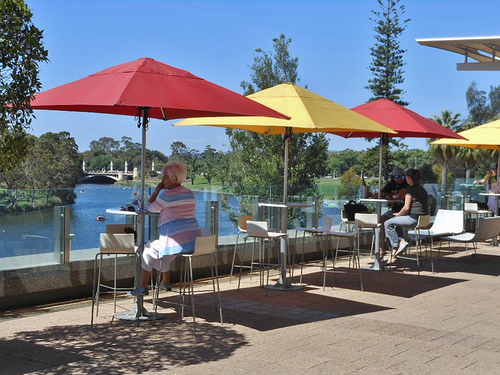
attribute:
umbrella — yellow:
[168, 80, 397, 137]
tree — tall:
[358, 14, 415, 226]